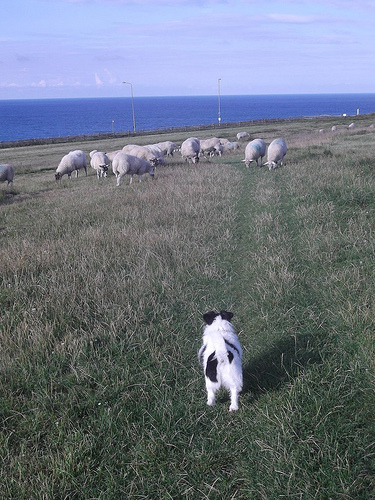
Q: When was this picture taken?
A: Daytime.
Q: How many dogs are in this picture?
A: 1.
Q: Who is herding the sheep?
A: The dog.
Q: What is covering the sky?
A: Clouds.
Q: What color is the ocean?
A: Blue.